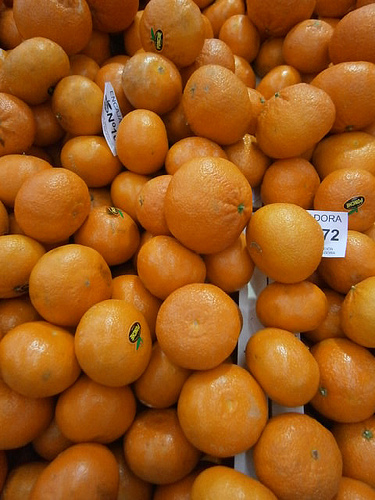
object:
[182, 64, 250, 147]
orange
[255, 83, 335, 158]
orange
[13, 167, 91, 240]
orange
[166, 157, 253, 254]
orange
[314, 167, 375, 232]
orange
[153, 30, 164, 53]
sticker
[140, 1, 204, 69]
orange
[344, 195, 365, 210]
sticker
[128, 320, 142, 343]
sticker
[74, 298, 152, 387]
orange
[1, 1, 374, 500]
cart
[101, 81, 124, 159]
price tag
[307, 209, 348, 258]
price tag